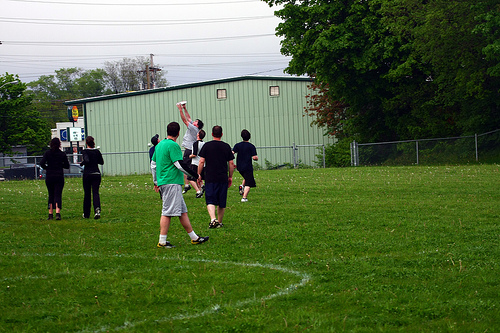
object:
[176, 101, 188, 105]
frisbee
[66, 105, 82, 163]
advertisements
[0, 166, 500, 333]
fence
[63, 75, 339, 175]
building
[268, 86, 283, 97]
window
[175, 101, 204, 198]
man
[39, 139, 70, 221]
woman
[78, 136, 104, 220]
woman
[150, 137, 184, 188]
shirt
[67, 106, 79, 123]
sign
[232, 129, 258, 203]
person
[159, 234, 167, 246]
sock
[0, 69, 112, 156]
tree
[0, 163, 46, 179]
vehicle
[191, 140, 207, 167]
shirt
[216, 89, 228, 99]
window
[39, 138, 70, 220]
person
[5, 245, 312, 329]
circle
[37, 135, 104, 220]
two girls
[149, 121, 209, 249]
boys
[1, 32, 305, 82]
powerline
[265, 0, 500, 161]
tree